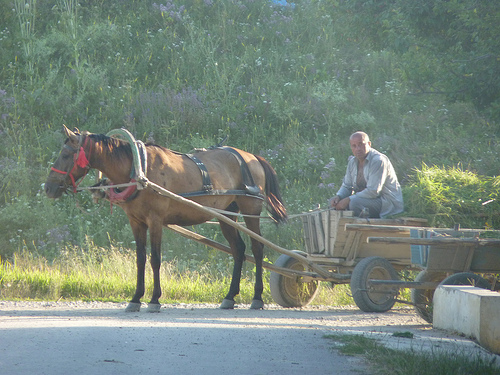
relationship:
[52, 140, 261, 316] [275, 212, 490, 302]
horse pulling buggy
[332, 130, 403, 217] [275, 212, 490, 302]
man in buggy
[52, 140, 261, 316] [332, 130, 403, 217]
horse pulling man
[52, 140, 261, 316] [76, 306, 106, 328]
horse on road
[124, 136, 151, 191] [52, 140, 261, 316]
yoke on horse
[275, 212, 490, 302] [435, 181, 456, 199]
buggy has grass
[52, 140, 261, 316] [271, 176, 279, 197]
horse moves tail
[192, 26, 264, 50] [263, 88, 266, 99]
hill has flowers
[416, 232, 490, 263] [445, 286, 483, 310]
cart near block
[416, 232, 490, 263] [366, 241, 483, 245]
cart has poles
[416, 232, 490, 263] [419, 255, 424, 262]
cart has planks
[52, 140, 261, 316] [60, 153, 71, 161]
horse has eyes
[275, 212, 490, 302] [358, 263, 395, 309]
buggy has wheel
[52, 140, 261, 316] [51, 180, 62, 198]
horse has mouth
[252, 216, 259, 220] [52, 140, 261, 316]
rope on horse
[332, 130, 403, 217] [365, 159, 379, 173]
man has shirt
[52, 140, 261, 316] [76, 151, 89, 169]
horse has bridle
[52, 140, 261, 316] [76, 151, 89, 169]
horse wearing bridle